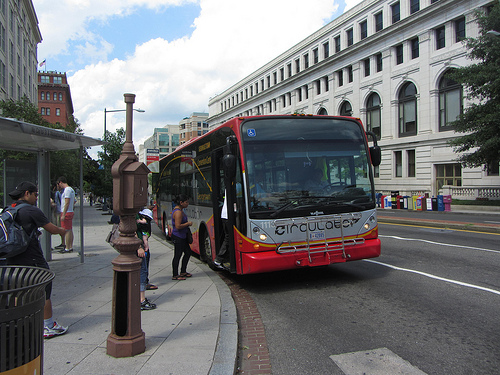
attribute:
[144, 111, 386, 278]
bus — at bus stop, stopped, red, gray, a city bus, public, at corner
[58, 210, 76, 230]
shorts — red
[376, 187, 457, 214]
newspaper machines — in a row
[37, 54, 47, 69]
flag — american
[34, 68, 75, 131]
building — multi story, brick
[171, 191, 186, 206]
hair — black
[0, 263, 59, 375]
garbage can — metal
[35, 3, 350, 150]
sky — blue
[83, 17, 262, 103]
clouds — white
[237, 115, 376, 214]
windshield — large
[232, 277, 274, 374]
design — brick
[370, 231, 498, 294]
paint — white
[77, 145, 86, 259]
post — metal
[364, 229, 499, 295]
line — white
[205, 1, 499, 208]
building — stone, multi story, white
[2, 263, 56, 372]
trash can — on corner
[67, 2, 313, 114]
cloud — white, large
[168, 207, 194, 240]
blouse — blue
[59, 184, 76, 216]
t-shirt — white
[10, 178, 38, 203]
baseball cap — black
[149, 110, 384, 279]
city bus — red, silver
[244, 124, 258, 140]
symbol — for handicap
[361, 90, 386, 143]
window — glass, rounded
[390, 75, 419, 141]
window — glass, rounded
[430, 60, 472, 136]
window — glass, rounded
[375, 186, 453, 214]
newspapers — various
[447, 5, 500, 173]
pine tree — green